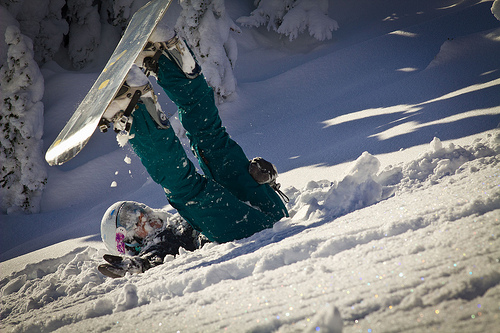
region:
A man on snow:
[105, 80, 249, 240]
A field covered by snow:
[180, 264, 269, 330]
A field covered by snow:
[330, 232, 480, 317]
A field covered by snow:
[330, 145, 467, 200]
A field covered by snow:
[280, 70, 412, 130]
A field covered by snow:
[47, 166, 129, 223]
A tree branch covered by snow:
[247, 0, 345, 46]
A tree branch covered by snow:
[2, 54, 57, 216]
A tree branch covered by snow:
[20, 6, 89, 46]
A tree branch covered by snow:
[172, 1, 249, 105]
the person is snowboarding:
[43, 0, 288, 278]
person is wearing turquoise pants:
[109, 53, 286, 243]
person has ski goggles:
[114, 198, 167, 253]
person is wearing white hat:
[93, 200, 138, 259]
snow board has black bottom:
[42, 0, 168, 169]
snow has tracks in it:
[0, 127, 498, 332]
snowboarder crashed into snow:
[45, 10, 294, 274]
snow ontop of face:
[113, 201, 164, 250]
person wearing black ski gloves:
[98, 155, 275, 278]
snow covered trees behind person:
[5, 0, 341, 213]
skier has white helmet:
[82, 191, 159, 268]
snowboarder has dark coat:
[151, 221, 202, 256]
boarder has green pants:
[122, 63, 292, 270]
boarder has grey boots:
[94, 11, 181, 129]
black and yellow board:
[61, 2, 168, 150]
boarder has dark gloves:
[226, 159, 280, 188]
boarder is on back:
[107, 167, 274, 279]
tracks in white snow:
[271, 143, 471, 277]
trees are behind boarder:
[8, 1, 114, 197]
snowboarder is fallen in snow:
[30, 27, 284, 270]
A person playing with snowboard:
[8, 0, 350, 317]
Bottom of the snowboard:
[90, 29, 119, 106]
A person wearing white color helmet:
[96, 193, 142, 250]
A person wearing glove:
[96, 251, 150, 281]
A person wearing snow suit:
[154, 153, 242, 240]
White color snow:
[346, 210, 448, 278]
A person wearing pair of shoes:
[97, 25, 193, 131]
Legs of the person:
[146, 108, 231, 173]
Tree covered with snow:
[4, 25, 36, 210]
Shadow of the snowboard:
[181, 186, 403, 274]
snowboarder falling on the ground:
[42, 7, 288, 279]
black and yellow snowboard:
[45, 0, 172, 167]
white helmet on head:
[100, 199, 165, 256]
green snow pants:
[121, 65, 290, 244]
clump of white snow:
[298, 145, 387, 216]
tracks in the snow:
[30, 200, 491, 315]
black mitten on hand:
[97, 252, 152, 281]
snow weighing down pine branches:
[177, 3, 242, 108]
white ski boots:
[98, 19, 197, 125]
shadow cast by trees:
[5, 64, 499, 221]